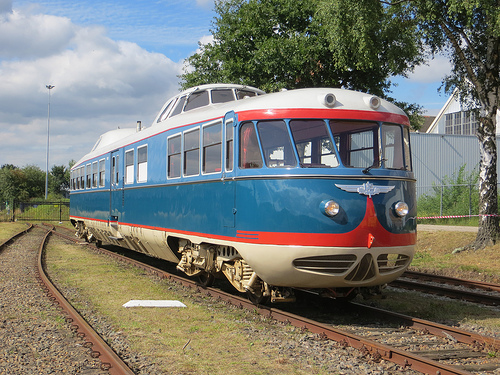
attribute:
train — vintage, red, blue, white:
[69, 120, 349, 306]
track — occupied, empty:
[389, 321, 432, 361]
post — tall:
[34, 145, 54, 187]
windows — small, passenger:
[441, 117, 465, 132]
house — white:
[433, 96, 474, 135]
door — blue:
[105, 145, 124, 216]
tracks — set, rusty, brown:
[417, 266, 475, 371]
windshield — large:
[330, 122, 379, 164]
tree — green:
[268, 10, 344, 71]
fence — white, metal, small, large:
[422, 130, 472, 177]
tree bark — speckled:
[457, 152, 496, 206]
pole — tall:
[39, 176, 54, 206]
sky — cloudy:
[186, 4, 196, 30]